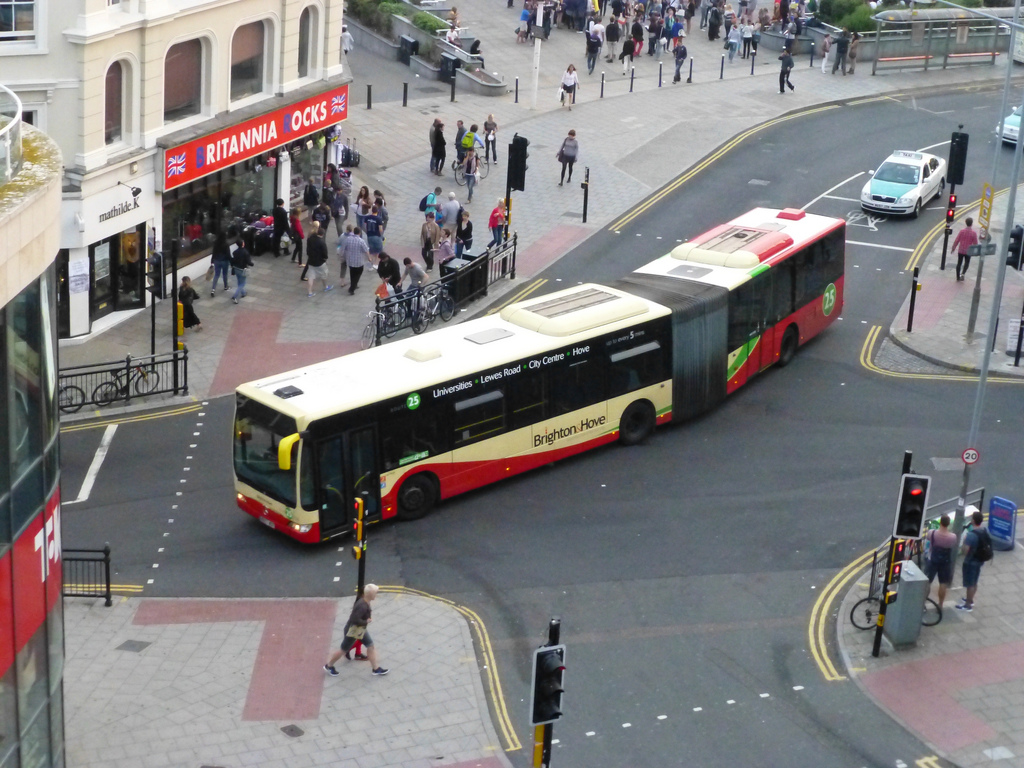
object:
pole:
[855, 444, 935, 659]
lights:
[891, 463, 931, 541]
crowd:
[520, 0, 867, 83]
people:
[765, 54, 797, 94]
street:
[547, 0, 1023, 206]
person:
[318, 581, 389, 680]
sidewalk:
[57, 604, 498, 767]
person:
[946, 513, 1001, 616]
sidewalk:
[842, 518, 1021, 757]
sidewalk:
[82, 293, 440, 378]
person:
[262, 186, 294, 259]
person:
[363, 206, 387, 274]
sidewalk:
[0, 48, 1002, 419]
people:
[278, 210, 311, 268]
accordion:
[598, 260, 737, 425]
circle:
[401, 389, 425, 413]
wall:
[3, 170, 68, 762]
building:
[0, 80, 110, 763]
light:
[883, 552, 908, 587]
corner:
[810, 434, 969, 687]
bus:
[227, 155, 866, 557]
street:
[126, 243, 1022, 752]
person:
[450, 124, 491, 183]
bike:
[448, 142, 495, 190]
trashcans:
[437, 251, 488, 306]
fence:
[372, 240, 519, 340]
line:
[73, 401, 122, 511]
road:
[27, 405, 291, 580]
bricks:
[114, 633, 160, 654]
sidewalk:
[61, 598, 466, 762]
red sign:
[149, 82, 352, 200]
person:
[552, 124, 585, 190]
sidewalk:
[338, 52, 637, 246]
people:
[221, 241, 257, 307]